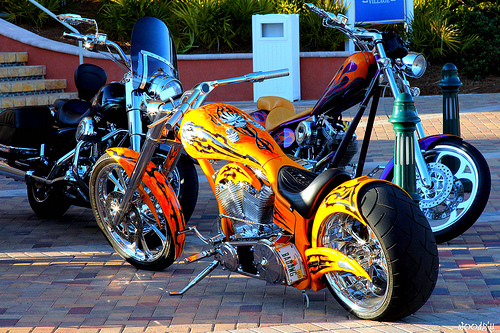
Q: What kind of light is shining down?
A: Sunlight.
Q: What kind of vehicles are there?
A: Motorcycles.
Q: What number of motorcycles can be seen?
A: Three.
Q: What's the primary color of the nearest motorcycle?
A: Yellow.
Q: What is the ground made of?
A: Brick.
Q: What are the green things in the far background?
A: Plants.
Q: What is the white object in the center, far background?
A: A trash bin.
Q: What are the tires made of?
A: Rubber.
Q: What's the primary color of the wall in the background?
A: Red.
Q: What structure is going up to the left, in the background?
A: Stairs.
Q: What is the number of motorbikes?
A: 3.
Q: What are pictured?
A: Motorcycles.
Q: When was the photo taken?
A: Yesterday.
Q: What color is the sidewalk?
A: Red.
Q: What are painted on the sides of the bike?
A: Flames.